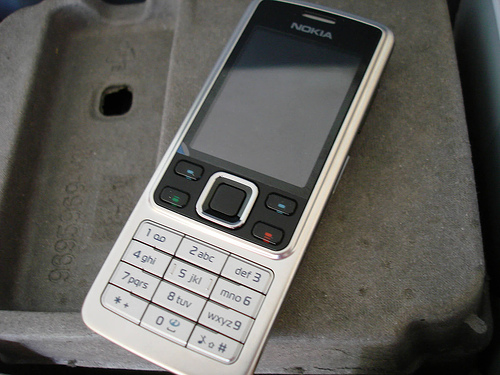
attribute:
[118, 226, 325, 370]
buttons — white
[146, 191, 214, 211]
line — green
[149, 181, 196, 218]
button — green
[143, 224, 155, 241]
number — printed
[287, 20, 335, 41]
writing — white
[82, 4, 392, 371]
cellphone — positioned at angle, turned off, silver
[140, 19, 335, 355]
phone — white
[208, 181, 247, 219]
button — black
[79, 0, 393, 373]
cell phone — Nokia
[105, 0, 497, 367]
cell phone — silver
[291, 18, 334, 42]
logo — Nokia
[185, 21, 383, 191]
screen — black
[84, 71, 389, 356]
cell phone — Nokia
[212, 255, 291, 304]
button — silver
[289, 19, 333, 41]
logo — silver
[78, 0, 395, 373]
phone — Nokia, grey, black, silver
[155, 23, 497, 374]
cellphone — silver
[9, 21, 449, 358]
sink — stone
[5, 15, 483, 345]
object — gray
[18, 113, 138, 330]
object — gray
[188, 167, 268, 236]
outline — silver